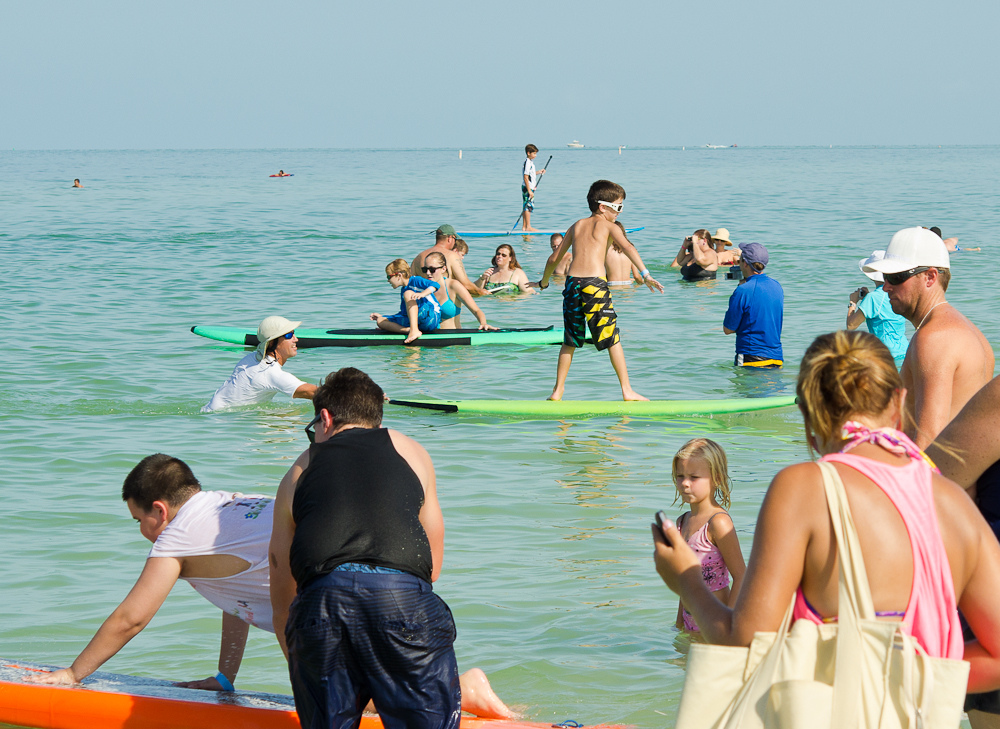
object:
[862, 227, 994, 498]
man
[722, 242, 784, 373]
man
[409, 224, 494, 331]
man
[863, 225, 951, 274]
hat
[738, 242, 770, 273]
hat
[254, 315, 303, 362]
hat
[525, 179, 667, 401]
boy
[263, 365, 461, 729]
boy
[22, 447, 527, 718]
boy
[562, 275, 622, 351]
surf shorts